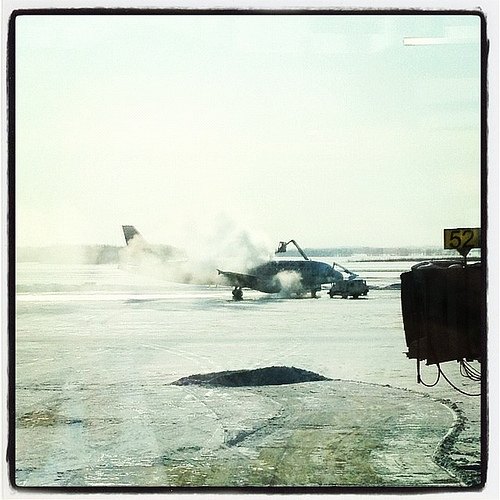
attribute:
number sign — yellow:
[443, 227, 485, 250]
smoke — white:
[122, 232, 272, 278]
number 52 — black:
[439, 217, 478, 256]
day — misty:
[18, 16, 479, 484]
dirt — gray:
[172, 365, 328, 386]